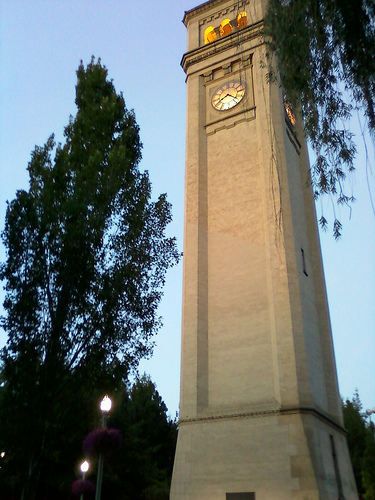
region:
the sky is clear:
[6, 0, 158, 51]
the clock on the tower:
[195, 73, 251, 112]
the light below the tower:
[90, 390, 116, 417]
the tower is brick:
[178, 2, 352, 495]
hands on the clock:
[210, 91, 241, 100]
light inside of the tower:
[205, 22, 212, 33]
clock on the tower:
[271, 95, 303, 123]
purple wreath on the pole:
[89, 422, 121, 453]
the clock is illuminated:
[196, 75, 260, 121]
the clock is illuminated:
[199, 76, 255, 121]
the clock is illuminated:
[199, 69, 279, 130]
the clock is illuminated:
[200, 59, 256, 131]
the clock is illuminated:
[202, 69, 267, 125]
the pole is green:
[91, 417, 114, 494]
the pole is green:
[95, 413, 109, 488]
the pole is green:
[84, 414, 129, 497]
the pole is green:
[85, 418, 116, 491]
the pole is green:
[80, 413, 118, 496]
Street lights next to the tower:
[73, 392, 121, 498]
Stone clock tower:
[168, 0, 360, 499]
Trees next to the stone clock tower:
[0, 0, 373, 499]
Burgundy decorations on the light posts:
[69, 427, 121, 494]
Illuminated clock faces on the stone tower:
[211, 78, 297, 127]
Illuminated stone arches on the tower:
[204, 9, 248, 43]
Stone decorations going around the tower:
[179, 0, 307, 72]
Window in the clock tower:
[301, 245, 308, 277]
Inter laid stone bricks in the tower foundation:
[168, 411, 358, 499]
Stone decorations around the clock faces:
[202, 53, 303, 154]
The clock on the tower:
[201, 59, 262, 141]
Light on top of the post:
[73, 376, 116, 427]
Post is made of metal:
[84, 423, 134, 496]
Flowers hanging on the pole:
[78, 422, 125, 458]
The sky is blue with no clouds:
[334, 262, 368, 332]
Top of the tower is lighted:
[199, 11, 275, 41]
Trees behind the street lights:
[22, 105, 252, 391]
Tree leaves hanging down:
[298, 81, 370, 245]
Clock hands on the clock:
[217, 86, 243, 113]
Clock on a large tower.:
[201, 78, 262, 118]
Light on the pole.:
[91, 391, 113, 499]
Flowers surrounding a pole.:
[72, 424, 127, 457]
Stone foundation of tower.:
[162, 412, 363, 497]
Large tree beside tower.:
[43, 53, 149, 412]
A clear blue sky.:
[29, 8, 106, 36]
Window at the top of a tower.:
[191, 13, 269, 41]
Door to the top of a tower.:
[324, 431, 351, 496]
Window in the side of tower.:
[294, 247, 321, 277]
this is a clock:
[206, 70, 262, 117]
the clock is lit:
[202, 69, 254, 119]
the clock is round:
[196, 60, 260, 134]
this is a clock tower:
[169, 4, 354, 497]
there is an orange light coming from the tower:
[188, 9, 281, 42]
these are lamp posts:
[62, 358, 121, 489]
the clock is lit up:
[203, 66, 251, 124]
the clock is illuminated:
[203, 68, 253, 115]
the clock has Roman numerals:
[203, 59, 248, 122]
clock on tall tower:
[203, 70, 263, 124]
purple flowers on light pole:
[80, 427, 129, 458]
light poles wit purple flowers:
[77, 384, 121, 497]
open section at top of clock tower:
[186, 7, 271, 54]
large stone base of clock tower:
[173, 348, 348, 498]